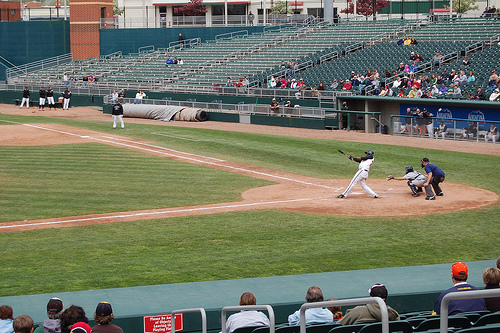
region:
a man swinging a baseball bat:
[323, 125, 382, 210]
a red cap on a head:
[443, 257, 478, 280]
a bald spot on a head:
[309, 285, 322, 297]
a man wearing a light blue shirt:
[220, 294, 270, 325]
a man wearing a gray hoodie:
[343, 274, 400, 326]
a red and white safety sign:
[135, 312, 177, 331]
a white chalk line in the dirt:
[39, 199, 205, 234]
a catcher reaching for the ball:
[376, 163, 429, 197]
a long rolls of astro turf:
[124, 102, 211, 124]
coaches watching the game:
[406, 104, 432, 133]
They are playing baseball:
[6, 5, 493, 325]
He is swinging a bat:
[327, 128, 377, 211]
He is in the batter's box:
[328, 133, 381, 208]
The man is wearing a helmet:
[360, 138, 385, 160]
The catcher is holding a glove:
[381, 168, 401, 197]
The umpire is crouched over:
[419, 153, 448, 213]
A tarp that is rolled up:
[124, 103, 206, 118]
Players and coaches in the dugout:
[366, 98, 493, 142]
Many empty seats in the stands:
[195, 17, 374, 65]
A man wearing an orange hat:
[440, 248, 481, 315]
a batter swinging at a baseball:
[326, 140, 384, 202]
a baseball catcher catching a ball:
[388, 160, 426, 201]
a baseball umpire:
[417, 154, 450, 199]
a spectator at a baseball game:
[218, 285, 270, 329]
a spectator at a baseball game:
[282, 285, 337, 330]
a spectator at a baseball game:
[343, 276, 394, 326]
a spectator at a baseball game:
[428, 258, 485, 326]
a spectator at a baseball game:
[86, 302, 132, 331]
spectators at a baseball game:
[3, 290, 130, 330]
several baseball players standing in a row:
[13, 80, 76, 114]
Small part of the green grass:
[229, 244, 259, 264]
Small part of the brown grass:
[288, 187, 299, 197]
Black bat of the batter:
[336, 148, 344, 154]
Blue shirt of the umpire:
[433, 165, 440, 174]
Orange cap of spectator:
[454, 262, 466, 274]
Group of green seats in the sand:
[281, 42, 310, 53]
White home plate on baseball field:
[352, 188, 362, 199]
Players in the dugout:
[463, 118, 498, 136]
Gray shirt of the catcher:
[412, 171, 418, 179]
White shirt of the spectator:
[239, 316, 251, 326]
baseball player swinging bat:
[329, 140, 379, 202]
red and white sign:
[141, 311, 184, 331]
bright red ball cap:
[449, 260, 469, 279]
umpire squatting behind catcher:
[417, 152, 447, 202]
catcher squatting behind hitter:
[387, 162, 425, 197]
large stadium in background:
[5, 12, 496, 120]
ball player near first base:
[110, 97, 127, 129]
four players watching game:
[15, 80, 72, 111]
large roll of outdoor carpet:
[115, 98, 205, 122]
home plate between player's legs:
[350, 186, 363, 196]